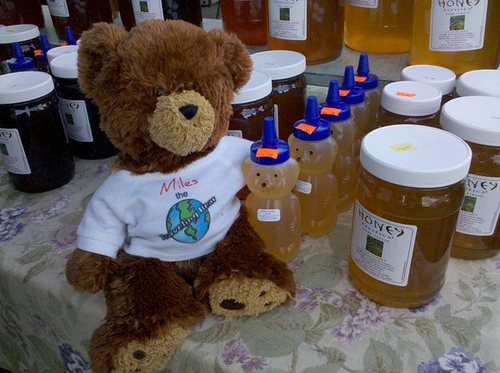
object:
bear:
[65, 18, 293, 371]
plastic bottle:
[337, 66, 370, 187]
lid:
[250, 116, 290, 166]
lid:
[293, 95, 330, 141]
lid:
[320, 80, 351, 122]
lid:
[356, 52, 378, 89]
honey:
[0, 70, 75, 193]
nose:
[178, 104, 196, 119]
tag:
[256, 148, 279, 160]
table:
[0, 84, 500, 373]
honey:
[229, 50, 500, 308]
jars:
[347, 63, 499, 306]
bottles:
[242, 54, 387, 264]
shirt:
[76, 136, 252, 261]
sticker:
[392, 143, 413, 151]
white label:
[349, 199, 416, 287]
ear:
[76, 21, 118, 96]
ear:
[209, 29, 252, 89]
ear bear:
[213, 16, 249, 105]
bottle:
[240, 117, 299, 265]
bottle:
[287, 94, 335, 237]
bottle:
[320, 77, 353, 214]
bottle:
[354, 52, 381, 129]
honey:
[0, 25, 109, 192]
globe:
[164, 197, 212, 245]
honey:
[349, 124, 470, 306]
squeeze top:
[338, 65, 365, 104]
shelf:
[200, 17, 412, 89]